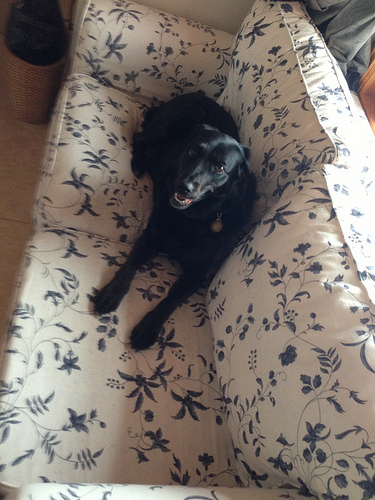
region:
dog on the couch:
[79, 99, 296, 316]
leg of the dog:
[86, 225, 168, 319]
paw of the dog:
[125, 310, 174, 366]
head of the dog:
[158, 114, 273, 217]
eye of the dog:
[202, 152, 237, 185]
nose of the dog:
[169, 175, 204, 202]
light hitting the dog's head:
[212, 135, 247, 167]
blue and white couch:
[61, 355, 192, 431]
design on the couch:
[33, 361, 228, 451]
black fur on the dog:
[178, 100, 208, 122]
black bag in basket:
[4, 3, 73, 121]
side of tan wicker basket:
[8, 48, 69, 126]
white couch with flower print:
[4, 2, 373, 498]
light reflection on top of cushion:
[290, 39, 373, 286]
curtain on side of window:
[316, 2, 373, 129]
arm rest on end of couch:
[73, 0, 236, 102]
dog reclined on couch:
[95, 91, 260, 347]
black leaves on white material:
[302, 346, 364, 412]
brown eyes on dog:
[169, 126, 239, 213]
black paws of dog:
[96, 254, 194, 353]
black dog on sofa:
[124, 61, 278, 282]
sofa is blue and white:
[62, 0, 355, 483]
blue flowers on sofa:
[86, 31, 327, 485]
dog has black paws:
[70, 235, 187, 365]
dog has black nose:
[177, 182, 194, 201]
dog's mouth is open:
[173, 181, 185, 211]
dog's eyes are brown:
[185, 131, 234, 182]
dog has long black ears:
[192, 134, 250, 212]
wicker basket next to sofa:
[5, 53, 70, 119]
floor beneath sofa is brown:
[1, 131, 51, 305]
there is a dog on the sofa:
[26, 11, 373, 496]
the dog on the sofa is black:
[91, 56, 271, 355]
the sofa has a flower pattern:
[47, 358, 279, 463]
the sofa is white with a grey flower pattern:
[86, 363, 341, 449]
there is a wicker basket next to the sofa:
[9, 29, 63, 124]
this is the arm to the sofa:
[85, 1, 246, 95]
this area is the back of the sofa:
[238, 25, 371, 469]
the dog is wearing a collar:
[188, 202, 240, 235]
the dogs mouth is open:
[169, 172, 204, 218]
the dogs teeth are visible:
[172, 191, 193, 214]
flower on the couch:
[102, 32, 135, 59]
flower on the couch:
[133, 422, 175, 455]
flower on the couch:
[55, 403, 103, 443]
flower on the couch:
[172, 391, 205, 423]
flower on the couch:
[275, 345, 307, 369]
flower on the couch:
[291, 371, 324, 399]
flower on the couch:
[60, 354, 83, 377]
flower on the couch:
[154, 330, 178, 355]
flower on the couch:
[262, 453, 292, 476]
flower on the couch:
[298, 419, 328, 450]